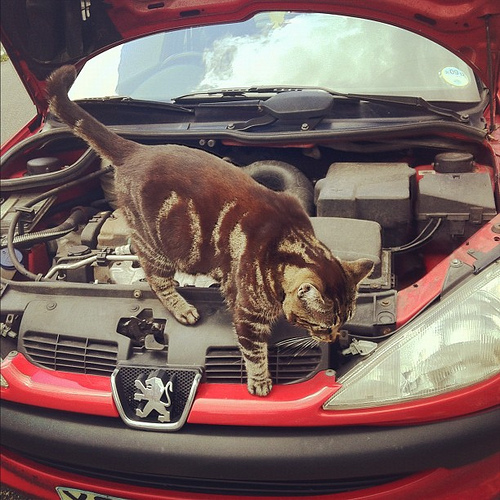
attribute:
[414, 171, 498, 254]
fuse box — closed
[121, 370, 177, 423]
car symbol — gray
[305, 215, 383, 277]
part — grey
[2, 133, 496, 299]
engine — car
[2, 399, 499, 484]
bumper — black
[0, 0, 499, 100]
hood — up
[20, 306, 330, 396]
grill — car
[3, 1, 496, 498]
car — red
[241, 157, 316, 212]
engine part — grey, plastic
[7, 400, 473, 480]
bumper — car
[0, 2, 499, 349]
open hood — red